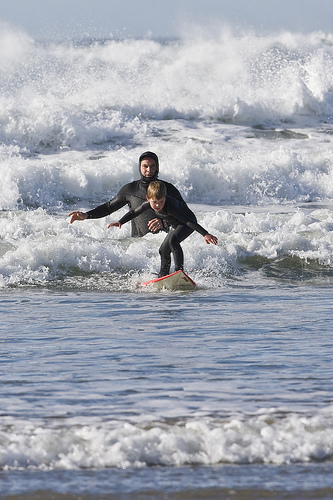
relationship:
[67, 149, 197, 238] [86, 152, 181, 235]
adult wearing wetsuit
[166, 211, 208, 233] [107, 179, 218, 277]
arm on a boy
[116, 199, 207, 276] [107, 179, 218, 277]
wetsuit on boy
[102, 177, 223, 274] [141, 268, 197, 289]
boy on surfboard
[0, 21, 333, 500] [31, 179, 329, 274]
water between waves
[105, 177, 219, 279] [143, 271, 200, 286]
boy on surfboard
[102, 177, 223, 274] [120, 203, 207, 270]
boy in wetsuit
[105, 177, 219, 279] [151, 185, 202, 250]
boy wearing wetsuit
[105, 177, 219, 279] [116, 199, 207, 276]
boy wearing wetsuit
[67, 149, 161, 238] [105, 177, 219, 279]
adult and boy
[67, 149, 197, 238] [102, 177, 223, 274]
adult teaching boy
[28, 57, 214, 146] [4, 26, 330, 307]
foam coming from waves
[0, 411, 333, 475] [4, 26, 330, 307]
foam coming from waves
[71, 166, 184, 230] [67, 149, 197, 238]
wetsuit on adult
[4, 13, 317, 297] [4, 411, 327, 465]
waves has foam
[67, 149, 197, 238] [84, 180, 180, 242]
adult has wetsuit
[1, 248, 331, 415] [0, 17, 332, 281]
water has waves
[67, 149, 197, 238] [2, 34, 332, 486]
adult in water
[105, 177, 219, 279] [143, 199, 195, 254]
boy wearing wet suit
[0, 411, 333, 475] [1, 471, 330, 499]
foam moving to shore